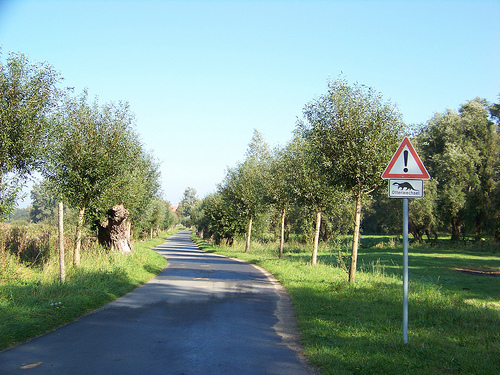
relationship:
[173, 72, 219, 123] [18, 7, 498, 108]
clouds in sky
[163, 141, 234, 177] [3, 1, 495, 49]
clouds in sky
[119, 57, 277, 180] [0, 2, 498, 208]
clouds in sky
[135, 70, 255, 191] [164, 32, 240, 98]
clouds in blue sky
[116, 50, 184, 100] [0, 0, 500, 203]
white clouds in sky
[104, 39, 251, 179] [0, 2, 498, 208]
clouds in sky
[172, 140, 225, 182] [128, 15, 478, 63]
white clouds in blue sky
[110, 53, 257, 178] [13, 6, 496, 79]
clouds in sky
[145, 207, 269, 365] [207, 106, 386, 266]
road near trees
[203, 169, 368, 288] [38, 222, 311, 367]
trees along road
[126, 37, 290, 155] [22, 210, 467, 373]
sky above ground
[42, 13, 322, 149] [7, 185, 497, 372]
sun in area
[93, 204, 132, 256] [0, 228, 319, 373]
tree stump near road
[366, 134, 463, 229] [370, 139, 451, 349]
sign on pole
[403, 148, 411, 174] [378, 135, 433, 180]
exclamation mark on street sign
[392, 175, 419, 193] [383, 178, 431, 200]
brontosaurus on sign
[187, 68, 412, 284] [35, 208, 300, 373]
trees on side of road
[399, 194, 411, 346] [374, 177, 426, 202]
pole underneath sign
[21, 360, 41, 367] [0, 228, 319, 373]
yellow spot on road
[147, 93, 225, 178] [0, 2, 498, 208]
white clouds in sky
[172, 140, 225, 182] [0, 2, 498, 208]
white clouds in sky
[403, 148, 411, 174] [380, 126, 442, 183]
exclamation mark on sign